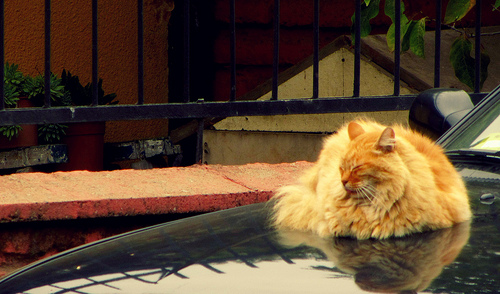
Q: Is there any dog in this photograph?
A: No, there are no dogs.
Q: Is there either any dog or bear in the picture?
A: No, there are no dogs or bears.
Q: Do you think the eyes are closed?
A: Yes, the eyes are closed.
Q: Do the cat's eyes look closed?
A: Yes, the eyes are closed.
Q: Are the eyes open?
A: No, the eyes are closed.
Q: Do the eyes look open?
A: No, the eyes are closed.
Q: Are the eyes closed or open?
A: The eyes are closed.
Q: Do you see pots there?
A: Yes, there is a pot.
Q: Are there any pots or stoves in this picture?
A: Yes, there is a pot.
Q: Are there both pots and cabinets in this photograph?
A: No, there is a pot but no cabinets.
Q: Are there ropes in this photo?
A: No, there are no ropes.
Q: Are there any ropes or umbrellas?
A: No, there are no ropes or umbrellas.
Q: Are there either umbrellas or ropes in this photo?
A: No, there are no ropes or umbrellas.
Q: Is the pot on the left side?
A: Yes, the pot is on the left of the image.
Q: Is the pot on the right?
A: No, the pot is on the left of the image.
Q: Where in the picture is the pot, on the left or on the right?
A: The pot is on the left of the image.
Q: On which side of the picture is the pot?
A: The pot is on the left of the image.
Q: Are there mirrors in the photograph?
A: Yes, there is a mirror.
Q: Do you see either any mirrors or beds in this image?
A: Yes, there is a mirror.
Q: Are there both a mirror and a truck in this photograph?
A: No, there is a mirror but no trucks.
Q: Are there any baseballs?
A: No, there are no baseballs.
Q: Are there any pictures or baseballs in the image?
A: No, there are no baseballs or pictures.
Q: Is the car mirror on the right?
A: Yes, the mirror is on the right of the image.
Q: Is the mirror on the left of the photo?
A: No, the mirror is on the right of the image.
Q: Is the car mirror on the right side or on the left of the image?
A: The mirror is on the right of the image.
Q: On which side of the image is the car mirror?
A: The mirror is on the right of the image.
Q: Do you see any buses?
A: No, there are no buses.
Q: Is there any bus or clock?
A: No, there are no buses or clocks.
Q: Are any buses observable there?
A: No, there are no buses.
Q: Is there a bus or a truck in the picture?
A: No, there are no buses or trucks.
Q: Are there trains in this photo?
A: No, there are no trains.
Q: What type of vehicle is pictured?
A: The vehicle is a car.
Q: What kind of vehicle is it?
A: The vehicle is a car.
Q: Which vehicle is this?
A: This is a car.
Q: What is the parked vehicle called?
A: The vehicle is a car.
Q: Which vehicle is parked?
A: The vehicle is a car.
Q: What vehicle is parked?
A: The vehicle is a car.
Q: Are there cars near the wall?
A: Yes, there is a car near the wall.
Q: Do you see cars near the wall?
A: Yes, there is a car near the wall.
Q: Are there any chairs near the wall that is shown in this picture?
A: No, there is a car near the wall.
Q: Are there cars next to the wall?
A: Yes, there is a car next to the wall.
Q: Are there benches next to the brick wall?
A: No, there is a car next to the wall.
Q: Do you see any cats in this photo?
A: Yes, there is a cat.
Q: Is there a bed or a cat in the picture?
A: Yes, there is a cat.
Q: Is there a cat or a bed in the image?
A: Yes, there is a cat.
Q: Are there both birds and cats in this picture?
A: No, there is a cat but no birds.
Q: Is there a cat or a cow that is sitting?
A: Yes, the cat is sitting.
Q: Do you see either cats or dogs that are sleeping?
A: Yes, the cat is sleeping.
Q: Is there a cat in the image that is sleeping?
A: Yes, there is a cat that is sleeping.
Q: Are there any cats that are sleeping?
A: Yes, there is a cat that is sleeping.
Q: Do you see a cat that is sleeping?
A: Yes, there is a cat that is sleeping.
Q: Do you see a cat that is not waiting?
A: Yes, there is a cat that is sleeping .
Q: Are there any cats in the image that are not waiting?
A: Yes, there is a cat that is sleeping.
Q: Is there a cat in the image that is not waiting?
A: Yes, there is a cat that is sleeping.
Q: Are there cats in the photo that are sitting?
A: Yes, there is a cat that is sitting.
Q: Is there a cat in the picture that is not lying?
A: Yes, there is a cat that is sitting.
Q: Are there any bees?
A: No, there are no bees.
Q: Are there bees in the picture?
A: No, there are no bees.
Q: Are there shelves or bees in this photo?
A: No, there are no bees or shelves.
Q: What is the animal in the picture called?
A: The animal is a cat.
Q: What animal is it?
A: The animal is a cat.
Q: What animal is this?
A: This is a cat.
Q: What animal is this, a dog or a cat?
A: This is a cat.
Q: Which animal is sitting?
A: The animal is a cat.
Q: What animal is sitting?
A: The animal is a cat.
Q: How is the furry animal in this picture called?
A: The animal is a cat.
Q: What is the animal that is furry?
A: The animal is a cat.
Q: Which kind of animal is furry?
A: The animal is a cat.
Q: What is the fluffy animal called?
A: The animal is a cat.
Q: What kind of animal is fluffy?
A: The animal is a cat.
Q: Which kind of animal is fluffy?
A: The animal is a cat.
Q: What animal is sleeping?
A: The animal is a cat.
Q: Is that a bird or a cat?
A: That is a cat.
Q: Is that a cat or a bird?
A: That is a cat.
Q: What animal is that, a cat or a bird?
A: That is a cat.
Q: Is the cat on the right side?
A: Yes, the cat is on the right of the image.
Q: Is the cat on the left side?
A: No, the cat is on the right of the image.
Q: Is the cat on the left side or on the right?
A: The cat is on the right of the image.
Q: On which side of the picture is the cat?
A: The cat is on the right of the image.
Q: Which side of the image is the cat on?
A: The cat is on the right of the image.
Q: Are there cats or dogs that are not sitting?
A: No, there is a cat but it is sitting.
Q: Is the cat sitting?
A: Yes, the cat is sitting.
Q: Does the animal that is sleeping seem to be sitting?
A: Yes, the cat is sitting.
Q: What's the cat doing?
A: The cat is sitting.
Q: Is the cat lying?
A: No, the cat is sitting.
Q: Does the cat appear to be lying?
A: No, the cat is sitting.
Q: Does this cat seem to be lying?
A: No, the cat is sitting.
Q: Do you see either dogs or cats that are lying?
A: No, there is a cat but it is sitting.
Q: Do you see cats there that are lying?
A: No, there is a cat but it is sitting.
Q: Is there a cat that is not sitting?
A: No, there is a cat but it is sitting.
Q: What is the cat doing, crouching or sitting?
A: The cat is sitting.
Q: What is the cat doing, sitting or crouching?
A: The cat is sitting.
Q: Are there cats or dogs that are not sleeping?
A: No, there is a cat but it is sleeping.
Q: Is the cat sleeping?
A: Yes, the cat is sleeping.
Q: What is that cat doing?
A: The cat is sleeping.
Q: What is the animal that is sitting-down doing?
A: The cat is sleeping.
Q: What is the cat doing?
A: The cat is sleeping.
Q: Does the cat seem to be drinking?
A: No, the cat is sleeping.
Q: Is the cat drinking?
A: No, the cat is sleeping.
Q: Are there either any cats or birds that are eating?
A: No, there is a cat but it is sleeping.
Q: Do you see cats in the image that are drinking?
A: No, there is a cat but it is sleeping.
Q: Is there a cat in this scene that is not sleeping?
A: No, there is a cat but it is sleeping.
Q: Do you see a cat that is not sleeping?
A: No, there is a cat but it is sleeping.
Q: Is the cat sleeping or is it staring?
A: The cat is sleeping.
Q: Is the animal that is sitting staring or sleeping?
A: The cat is sleeping.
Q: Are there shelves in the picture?
A: No, there are no shelves.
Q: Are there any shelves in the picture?
A: No, there are no shelves.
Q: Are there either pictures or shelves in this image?
A: No, there are no shelves or pictures.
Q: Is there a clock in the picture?
A: No, there are no clocks.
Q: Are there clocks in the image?
A: No, there are no clocks.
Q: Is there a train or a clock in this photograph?
A: No, there are no clocks or trains.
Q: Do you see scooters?
A: No, there are no scooters.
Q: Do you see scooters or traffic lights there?
A: No, there are no scooters or traffic lights.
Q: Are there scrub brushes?
A: No, there are no scrub brushes.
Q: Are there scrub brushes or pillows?
A: No, there are no scrub brushes or pillows.